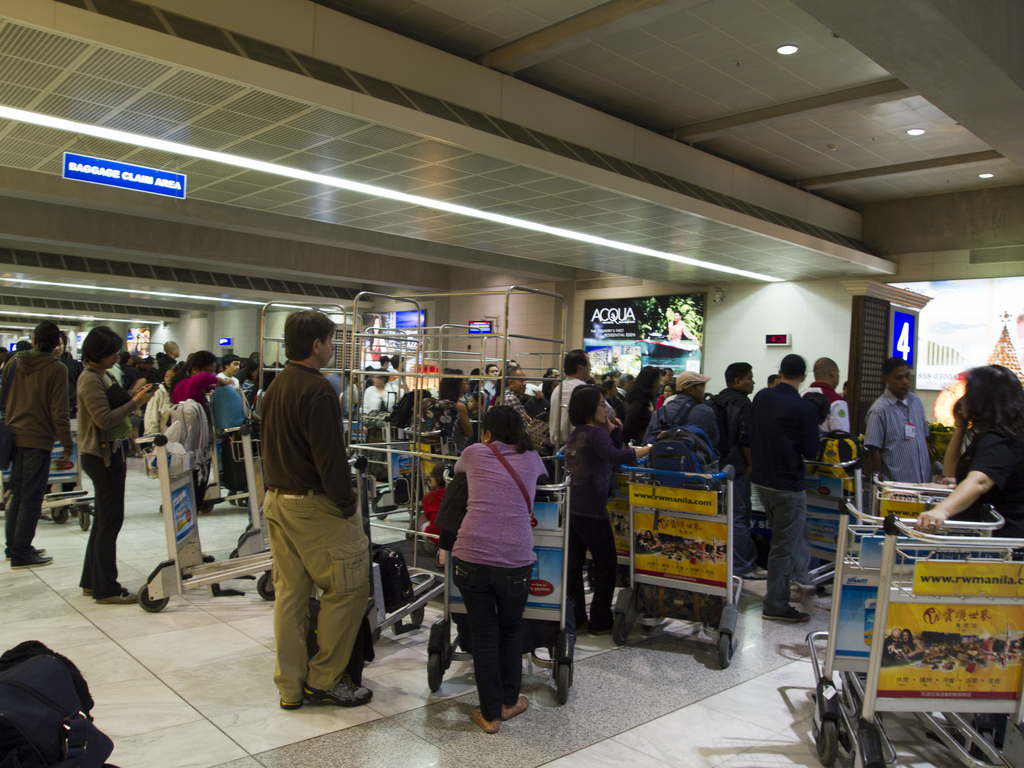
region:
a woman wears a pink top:
[410, 398, 611, 747]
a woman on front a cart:
[416, 406, 598, 751]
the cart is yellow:
[607, 436, 756, 684]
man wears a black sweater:
[752, 344, 825, 624]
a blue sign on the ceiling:
[56, 129, 200, 205]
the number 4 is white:
[891, 300, 930, 365]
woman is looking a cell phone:
[65, 319, 168, 614]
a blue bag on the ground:
[0, 628, 130, 765]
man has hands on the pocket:
[245, 300, 385, 724]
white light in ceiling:
[157, 126, 807, 320]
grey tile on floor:
[530, 654, 709, 752]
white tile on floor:
[81, 585, 218, 753]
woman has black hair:
[465, 404, 529, 466]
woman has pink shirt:
[454, 455, 546, 573]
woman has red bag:
[424, 445, 539, 569]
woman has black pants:
[454, 562, 534, 693]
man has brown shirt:
[244, 380, 340, 511]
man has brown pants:
[239, 508, 388, 717]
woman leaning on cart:
[417, 471, 583, 715]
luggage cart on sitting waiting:
[127, 428, 283, 612]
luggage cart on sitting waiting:
[36, 419, 100, 522]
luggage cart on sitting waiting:
[337, 472, 442, 656]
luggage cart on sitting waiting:
[226, 416, 285, 576]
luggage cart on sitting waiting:
[373, 427, 441, 517]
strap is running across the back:
[478, 444, 554, 528]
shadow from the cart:
[690, 667, 830, 766]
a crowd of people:
[2, 275, 1023, 741]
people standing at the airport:
[0, 301, 1021, 734]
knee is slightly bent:
[337, 567, 383, 625]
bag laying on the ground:
[0, 633, 125, 766]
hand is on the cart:
[908, 500, 947, 535]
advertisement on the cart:
[621, 482, 739, 600]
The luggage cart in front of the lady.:
[136, 420, 270, 614]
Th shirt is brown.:
[255, 364, 350, 491]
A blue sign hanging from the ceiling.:
[44, 140, 201, 220]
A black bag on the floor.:
[19, 630, 144, 754]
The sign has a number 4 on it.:
[887, 294, 929, 361]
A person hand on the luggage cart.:
[913, 471, 1022, 545]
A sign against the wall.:
[544, 284, 740, 390]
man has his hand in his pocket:
[279, 453, 381, 531]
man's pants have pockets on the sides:
[326, 533, 371, 599]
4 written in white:
[885, 310, 920, 372]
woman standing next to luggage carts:
[834, 361, 1022, 763]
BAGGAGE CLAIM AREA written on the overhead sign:
[40, 137, 190, 208]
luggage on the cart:
[355, 526, 432, 616]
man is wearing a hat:
[679, 360, 712, 403]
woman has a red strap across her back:
[466, 437, 563, 552]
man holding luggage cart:
[225, 294, 393, 725]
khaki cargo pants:
[238, 465, 382, 706]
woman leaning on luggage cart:
[425, 398, 582, 744]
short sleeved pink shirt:
[446, 429, 546, 565]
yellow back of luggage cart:
[867, 525, 1022, 719]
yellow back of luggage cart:
[615, 478, 737, 586]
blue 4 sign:
[886, 300, 932, 376]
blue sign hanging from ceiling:
[52, 152, 207, 210]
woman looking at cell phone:
[61, 306, 170, 620]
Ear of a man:
[305, 334, 326, 357]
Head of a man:
[272, 303, 345, 381]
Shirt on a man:
[247, 351, 369, 520]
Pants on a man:
[249, 492, 377, 718]